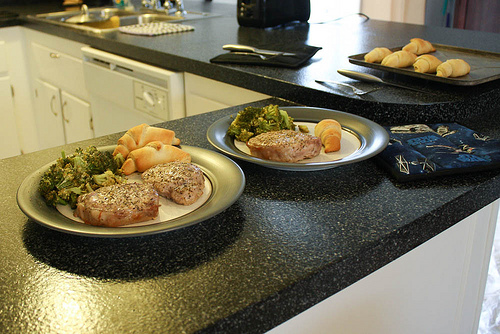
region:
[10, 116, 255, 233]
this is a plate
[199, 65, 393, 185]
this is a plate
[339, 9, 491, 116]
this is a tray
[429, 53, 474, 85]
this is a pie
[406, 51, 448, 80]
this is a pie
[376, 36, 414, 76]
this is a pie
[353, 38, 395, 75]
this is a pie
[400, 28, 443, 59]
this is a pie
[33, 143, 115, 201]
these are vegetables in a plate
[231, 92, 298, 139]
these are vegetables in a plate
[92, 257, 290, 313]
the counter top is black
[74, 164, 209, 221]
two pieces of meat on a plate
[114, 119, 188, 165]
two crescent rolls on the plate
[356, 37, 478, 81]
crescent rolls on black tray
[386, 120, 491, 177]
square pot holder on table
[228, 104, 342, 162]
plate of food with one on everthing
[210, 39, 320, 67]
knife and fork on a black napkin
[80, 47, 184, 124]
the dish washer is white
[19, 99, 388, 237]
two plates of food on the counter top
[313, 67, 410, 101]
knife and fork not on a napkin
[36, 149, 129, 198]
pile of green broccoli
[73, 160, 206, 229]
two pieces of meat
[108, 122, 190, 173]
two golden brown croissants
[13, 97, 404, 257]
two plates on the counter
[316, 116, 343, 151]
one croissant on the plate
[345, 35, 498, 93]
croissants on a pan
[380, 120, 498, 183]
oven mitt on the counter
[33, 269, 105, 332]
light glare on the countertop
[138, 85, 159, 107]
knob on the dishwasher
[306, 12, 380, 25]
cord hanging down from the counter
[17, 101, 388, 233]
Plates of food on the counter.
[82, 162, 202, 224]
Seasoned meat on a plate.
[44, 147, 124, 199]
Mound of broccoli.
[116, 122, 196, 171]
Two golden brown croissant rolls.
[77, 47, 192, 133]
White dishwasher under the counter.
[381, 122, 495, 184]
A blue oven mit.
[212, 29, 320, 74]
Silverware on a black napkin.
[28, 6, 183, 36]
A stainless steel kitchen sink.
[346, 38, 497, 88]
Croissant rolls on a pan.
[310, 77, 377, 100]
A silver fork on the counter.